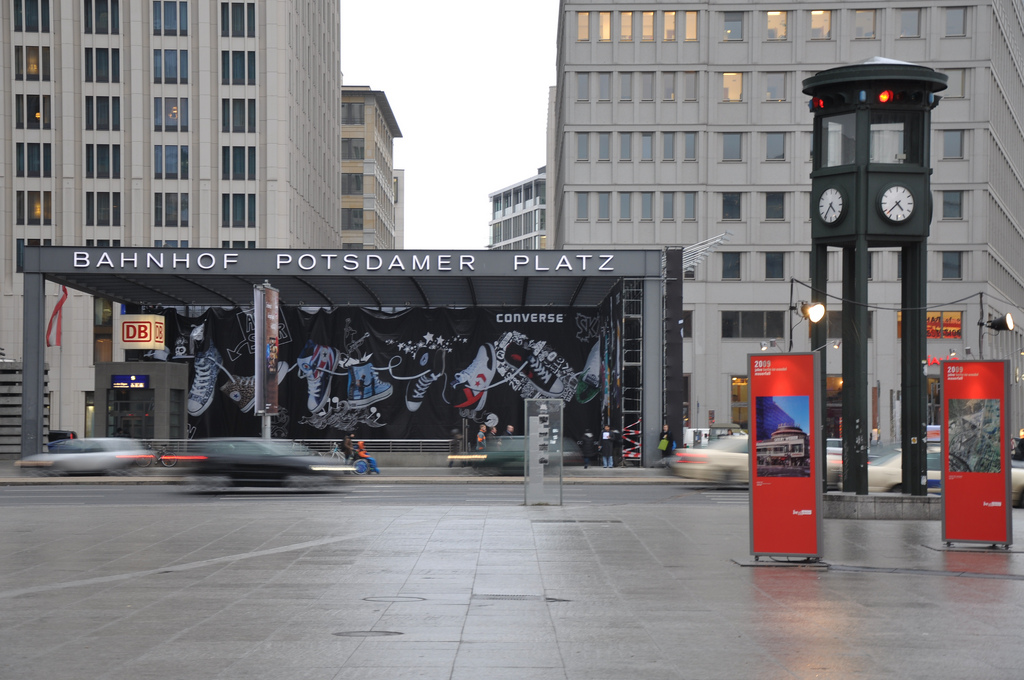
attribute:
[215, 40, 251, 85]
cabinet — white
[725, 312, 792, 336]
cabinet — wood, white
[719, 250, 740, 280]
cabinet — white, wood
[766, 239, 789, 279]
cabinet — wood, white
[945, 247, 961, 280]
cabinet — white, wood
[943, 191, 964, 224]
cabinet — wood, white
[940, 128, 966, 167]
cabinet — white, wood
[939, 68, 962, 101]
cabinet — wood, white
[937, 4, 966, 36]
cabinet — wood, white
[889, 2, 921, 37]
cabinet — wood , white